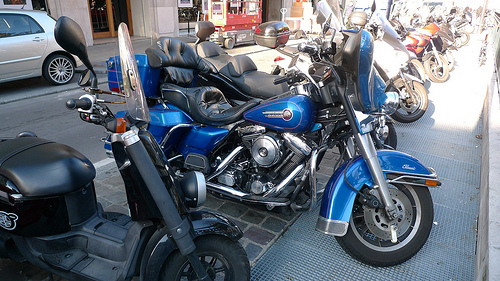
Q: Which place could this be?
A: It is a road.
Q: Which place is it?
A: It is a road.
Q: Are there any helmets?
A: No, there are no helmets.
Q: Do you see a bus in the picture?
A: No, there are no buses.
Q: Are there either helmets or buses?
A: No, there are no buses or helmets.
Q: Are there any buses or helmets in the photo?
A: No, there are no buses or helmets.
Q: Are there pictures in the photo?
A: No, there are no pictures.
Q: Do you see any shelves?
A: No, there are no shelves.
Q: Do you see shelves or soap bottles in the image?
A: No, there are no shelves or soap bottles.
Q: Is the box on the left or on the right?
A: The box is on the left of the image.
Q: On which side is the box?
A: The box is on the left of the image.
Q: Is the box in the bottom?
A: No, the box is in the top of the image.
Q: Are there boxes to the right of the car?
A: Yes, there is a box to the right of the car.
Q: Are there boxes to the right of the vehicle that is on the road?
A: Yes, there is a box to the right of the car.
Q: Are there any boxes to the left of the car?
A: No, the box is to the right of the car.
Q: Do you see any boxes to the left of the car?
A: No, the box is to the right of the car.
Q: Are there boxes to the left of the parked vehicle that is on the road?
A: No, the box is to the right of the car.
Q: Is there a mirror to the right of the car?
A: No, there is a box to the right of the car.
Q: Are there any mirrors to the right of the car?
A: No, there is a box to the right of the car.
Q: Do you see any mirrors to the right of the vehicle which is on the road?
A: No, there is a box to the right of the car.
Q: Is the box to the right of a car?
A: Yes, the box is to the right of a car.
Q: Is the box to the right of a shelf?
A: No, the box is to the right of a car.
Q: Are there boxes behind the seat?
A: Yes, there is a box behind the seat.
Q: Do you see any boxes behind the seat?
A: Yes, there is a box behind the seat.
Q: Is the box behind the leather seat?
A: Yes, the box is behind the seat.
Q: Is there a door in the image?
A: Yes, there is a door.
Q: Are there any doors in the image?
A: Yes, there is a door.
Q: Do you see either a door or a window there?
A: Yes, there is a door.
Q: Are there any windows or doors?
A: Yes, there is a door.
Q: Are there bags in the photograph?
A: No, there are no bags.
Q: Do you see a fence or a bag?
A: No, there are no bags or fences.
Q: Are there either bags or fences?
A: No, there are no bags or fences.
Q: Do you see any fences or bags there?
A: No, there are no bags or fences.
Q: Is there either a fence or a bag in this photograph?
A: No, there are no bags or fences.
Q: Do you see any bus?
A: No, there are no buses.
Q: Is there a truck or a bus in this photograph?
A: No, there are no buses or trucks.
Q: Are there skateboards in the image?
A: No, there are no skateboards.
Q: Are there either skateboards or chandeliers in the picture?
A: No, there are no skateboards or chandeliers.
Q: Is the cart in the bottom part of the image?
A: No, the cart is in the top of the image.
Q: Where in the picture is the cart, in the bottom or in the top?
A: The cart is in the top of the image.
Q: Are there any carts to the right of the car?
A: Yes, there is a cart to the right of the car.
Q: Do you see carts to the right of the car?
A: Yes, there is a cart to the right of the car.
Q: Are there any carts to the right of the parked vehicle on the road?
A: Yes, there is a cart to the right of the car.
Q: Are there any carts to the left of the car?
A: No, the cart is to the right of the car.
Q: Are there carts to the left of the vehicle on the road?
A: No, the cart is to the right of the car.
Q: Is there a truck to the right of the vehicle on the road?
A: No, there is a cart to the right of the car.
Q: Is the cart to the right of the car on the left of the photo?
A: Yes, the cart is to the right of the car.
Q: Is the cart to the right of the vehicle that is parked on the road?
A: Yes, the cart is to the right of the car.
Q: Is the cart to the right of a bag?
A: No, the cart is to the right of the car.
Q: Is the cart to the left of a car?
A: No, the cart is to the right of a car.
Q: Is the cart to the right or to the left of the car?
A: The cart is to the right of the car.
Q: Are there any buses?
A: No, there are no buses.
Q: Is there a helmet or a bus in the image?
A: No, there are no buses or helmets.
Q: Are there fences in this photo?
A: No, there are no fences.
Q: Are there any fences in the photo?
A: No, there are no fences.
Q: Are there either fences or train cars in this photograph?
A: No, there are no fences or train cars.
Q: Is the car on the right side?
A: No, the car is on the left of the image.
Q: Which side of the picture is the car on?
A: The car is on the left of the image.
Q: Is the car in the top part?
A: Yes, the car is in the top of the image.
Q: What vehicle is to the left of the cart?
A: The vehicle is a car.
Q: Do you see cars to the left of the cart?
A: Yes, there is a car to the left of the cart.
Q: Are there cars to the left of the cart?
A: Yes, there is a car to the left of the cart.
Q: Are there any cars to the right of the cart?
A: No, the car is to the left of the cart.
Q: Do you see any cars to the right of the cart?
A: No, the car is to the left of the cart.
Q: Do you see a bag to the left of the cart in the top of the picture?
A: No, there is a car to the left of the cart.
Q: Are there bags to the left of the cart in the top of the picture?
A: No, there is a car to the left of the cart.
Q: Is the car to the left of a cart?
A: Yes, the car is to the left of a cart.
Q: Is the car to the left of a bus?
A: No, the car is to the left of a cart.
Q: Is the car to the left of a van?
A: No, the car is to the left of the motorbike.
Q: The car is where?
A: The car is on the road.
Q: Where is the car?
A: The car is on the road.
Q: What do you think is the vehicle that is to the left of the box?
A: The vehicle is a car.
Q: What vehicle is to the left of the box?
A: The vehicle is a car.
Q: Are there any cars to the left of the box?
A: Yes, there is a car to the left of the box.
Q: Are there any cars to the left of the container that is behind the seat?
A: Yes, there is a car to the left of the box.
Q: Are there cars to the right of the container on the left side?
A: No, the car is to the left of the box.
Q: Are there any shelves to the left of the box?
A: No, there is a car to the left of the box.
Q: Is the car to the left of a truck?
A: No, the car is to the left of the box.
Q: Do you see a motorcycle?
A: Yes, there is a motorcycle.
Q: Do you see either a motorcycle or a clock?
A: Yes, there is a motorcycle.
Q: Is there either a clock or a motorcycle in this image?
A: Yes, there is a motorcycle.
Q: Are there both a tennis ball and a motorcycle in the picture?
A: No, there is a motorcycle but no tennis balls.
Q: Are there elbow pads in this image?
A: No, there are no elbow pads.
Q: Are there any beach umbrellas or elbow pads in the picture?
A: No, there are no elbow pads or beach umbrellas.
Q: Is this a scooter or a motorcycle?
A: This is a motorcycle.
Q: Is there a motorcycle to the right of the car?
A: Yes, there is a motorcycle to the right of the car.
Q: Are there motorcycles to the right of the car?
A: Yes, there is a motorcycle to the right of the car.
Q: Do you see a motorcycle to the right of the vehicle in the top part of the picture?
A: Yes, there is a motorcycle to the right of the car.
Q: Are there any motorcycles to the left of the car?
A: No, the motorcycle is to the right of the car.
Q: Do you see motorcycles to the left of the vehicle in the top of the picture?
A: No, the motorcycle is to the right of the car.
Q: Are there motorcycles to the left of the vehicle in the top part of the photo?
A: No, the motorcycle is to the right of the car.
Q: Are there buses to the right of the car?
A: No, there is a motorcycle to the right of the car.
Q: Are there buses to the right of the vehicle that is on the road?
A: No, there is a motorcycle to the right of the car.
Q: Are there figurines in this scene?
A: No, there are no figurines.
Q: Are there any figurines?
A: No, there are no figurines.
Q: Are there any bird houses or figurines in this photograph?
A: No, there are no figurines or bird houses.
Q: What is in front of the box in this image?
A: The seat is in front of the box.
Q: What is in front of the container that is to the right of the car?
A: The seat is in front of the box.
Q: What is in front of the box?
A: The seat is in front of the box.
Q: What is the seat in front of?
A: The seat is in front of the box.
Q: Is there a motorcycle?
A: Yes, there are motorcycles.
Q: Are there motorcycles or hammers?
A: Yes, there are motorcycles.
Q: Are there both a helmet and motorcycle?
A: No, there are motorcycles but no helmets.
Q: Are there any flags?
A: No, there are no flags.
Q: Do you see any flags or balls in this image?
A: No, there are no flags or balls.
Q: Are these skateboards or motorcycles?
A: These are motorcycles.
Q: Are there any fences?
A: No, there are no fences.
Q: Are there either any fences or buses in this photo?
A: No, there are no fences or buses.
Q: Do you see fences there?
A: No, there are no fences.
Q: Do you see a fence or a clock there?
A: No, there are no fences or clocks.